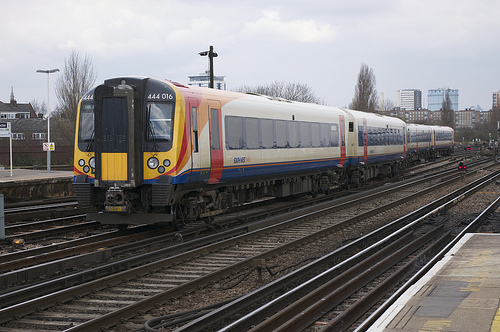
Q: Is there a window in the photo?
A: Yes, there are windows.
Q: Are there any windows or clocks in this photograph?
A: Yes, there are windows.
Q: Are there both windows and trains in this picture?
A: Yes, there are both windows and a train.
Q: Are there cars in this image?
A: No, there are no cars.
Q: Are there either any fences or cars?
A: No, there are no cars or fences.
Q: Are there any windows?
A: Yes, there are windows.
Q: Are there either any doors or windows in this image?
A: Yes, there are windows.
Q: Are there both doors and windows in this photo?
A: Yes, there are both windows and doors.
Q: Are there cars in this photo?
A: No, there are no cars.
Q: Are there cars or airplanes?
A: No, there are no cars or airplanes.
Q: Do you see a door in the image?
A: Yes, there is a door.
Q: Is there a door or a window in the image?
A: Yes, there is a door.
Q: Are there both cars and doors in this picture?
A: No, there is a door but no cars.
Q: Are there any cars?
A: No, there are no cars.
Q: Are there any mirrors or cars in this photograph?
A: No, there are no cars or mirrors.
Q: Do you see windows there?
A: Yes, there are windows.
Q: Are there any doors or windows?
A: Yes, there are windows.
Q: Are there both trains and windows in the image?
A: Yes, there are both windows and a train.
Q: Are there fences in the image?
A: No, there are no fences.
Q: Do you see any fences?
A: No, there are no fences.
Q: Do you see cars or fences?
A: No, there are no fences or cars.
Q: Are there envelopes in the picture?
A: No, there are no envelopes.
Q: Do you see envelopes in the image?
A: No, there are no envelopes.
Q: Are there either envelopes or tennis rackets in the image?
A: No, there are no envelopes or tennis rackets.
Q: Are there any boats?
A: No, there are no boats.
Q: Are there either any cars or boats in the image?
A: No, there are no boats or cars.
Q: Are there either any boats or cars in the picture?
A: No, there are no boats or cars.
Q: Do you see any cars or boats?
A: No, there are no boats or cars.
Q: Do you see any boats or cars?
A: No, there are no boats or cars.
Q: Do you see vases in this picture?
A: No, there are no vases.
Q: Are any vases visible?
A: No, there are no vases.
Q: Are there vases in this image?
A: No, there are no vases.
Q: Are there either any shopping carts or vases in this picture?
A: No, there are no vases or shopping carts.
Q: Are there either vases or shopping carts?
A: No, there are no vases or shopping carts.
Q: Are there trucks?
A: No, there are no trucks.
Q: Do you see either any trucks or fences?
A: No, there are no trucks or fences.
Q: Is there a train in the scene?
A: Yes, there is a train.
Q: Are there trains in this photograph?
A: Yes, there is a train.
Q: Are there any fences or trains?
A: Yes, there is a train.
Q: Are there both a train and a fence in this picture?
A: No, there is a train but no fences.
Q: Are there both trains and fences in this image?
A: No, there is a train but no fences.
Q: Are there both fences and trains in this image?
A: No, there is a train but no fences.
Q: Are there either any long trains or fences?
A: Yes, there is a long train.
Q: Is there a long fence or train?
A: Yes, there is a long train.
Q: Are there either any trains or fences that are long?
A: Yes, the train is long.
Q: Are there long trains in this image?
A: Yes, there is a long train.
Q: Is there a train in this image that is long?
A: Yes, there is a train that is long.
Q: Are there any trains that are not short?
A: Yes, there is a long train.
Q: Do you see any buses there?
A: No, there are no buses.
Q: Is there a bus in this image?
A: No, there are no buses.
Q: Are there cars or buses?
A: No, there are no buses or cars.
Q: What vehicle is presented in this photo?
A: The vehicle is a train.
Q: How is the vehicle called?
A: The vehicle is a train.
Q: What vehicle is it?
A: The vehicle is a train.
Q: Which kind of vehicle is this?
A: This is a train.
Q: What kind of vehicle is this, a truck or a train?
A: This is a train.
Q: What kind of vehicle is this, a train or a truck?
A: This is a train.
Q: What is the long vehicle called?
A: The vehicle is a train.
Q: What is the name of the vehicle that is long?
A: The vehicle is a train.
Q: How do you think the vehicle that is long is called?
A: The vehicle is a train.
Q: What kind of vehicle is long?
A: The vehicle is a train.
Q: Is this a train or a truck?
A: This is a train.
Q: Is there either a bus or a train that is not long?
A: No, there is a train but it is long.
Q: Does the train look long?
A: Yes, the train is long.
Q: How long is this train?
A: The train is long.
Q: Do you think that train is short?
A: No, the train is long.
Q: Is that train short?
A: No, the train is long.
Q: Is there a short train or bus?
A: No, there is a train but it is long.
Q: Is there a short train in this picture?
A: No, there is a train but it is long.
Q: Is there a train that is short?
A: No, there is a train but it is long.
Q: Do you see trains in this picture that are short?
A: No, there is a train but it is long.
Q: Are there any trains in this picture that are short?
A: No, there is a train but it is long.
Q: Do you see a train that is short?
A: No, there is a train but it is long.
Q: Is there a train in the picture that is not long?
A: No, there is a train but it is long.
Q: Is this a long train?
A: Yes, this is a long train.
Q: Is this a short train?
A: No, this is a long train.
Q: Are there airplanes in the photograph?
A: No, there are no airplanes.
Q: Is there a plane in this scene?
A: No, there are no airplanes.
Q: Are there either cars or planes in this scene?
A: No, there are no planes or cars.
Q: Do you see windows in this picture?
A: Yes, there are windows.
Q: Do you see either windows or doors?
A: Yes, there are windows.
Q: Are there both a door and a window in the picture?
A: Yes, there are both a window and a door.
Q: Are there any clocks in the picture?
A: No, there are no clocks.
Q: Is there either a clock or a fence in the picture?
A: No, there are no clocks or fences.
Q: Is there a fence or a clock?
A: No, there are no clocks or fences.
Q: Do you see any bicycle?
A: No, there are no bicycles.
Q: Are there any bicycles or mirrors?
A: No, there are no bicycles or mirrors.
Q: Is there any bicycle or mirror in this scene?
A: No, there are no bicycles or mirrors.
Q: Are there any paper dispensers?
A: No, there are no paper dispensers.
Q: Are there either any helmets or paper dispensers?
A: No, there are no paper dispensers or helmets.